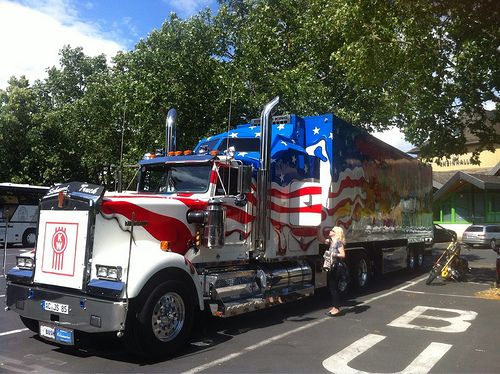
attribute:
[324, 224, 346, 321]
woman — standing, reaching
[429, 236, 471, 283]
motorbike — tilted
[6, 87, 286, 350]
truck — red, white, blue, parked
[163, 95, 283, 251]
pipes — chrome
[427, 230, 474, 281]
motorcycle — parked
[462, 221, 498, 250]
car — gray, parked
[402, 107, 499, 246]
building — green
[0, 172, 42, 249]
bus — parked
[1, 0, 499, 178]
trees — growing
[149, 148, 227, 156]
lights — mounted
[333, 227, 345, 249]
hair — white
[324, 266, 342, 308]
pants — black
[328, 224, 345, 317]
person — standing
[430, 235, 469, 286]
bike — parked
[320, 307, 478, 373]
bu — painted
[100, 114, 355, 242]
flag — painted